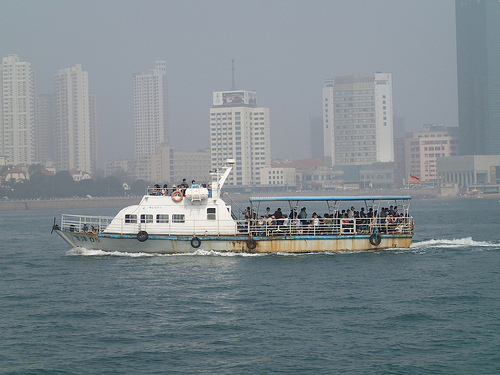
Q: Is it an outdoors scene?
A: Yes, it is outdoors.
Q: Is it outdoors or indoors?
A: It is outdoors.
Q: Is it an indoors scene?
A: No, it is outdoors.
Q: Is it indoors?
A: No, it is outdoors.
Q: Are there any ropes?
A: No, there are no ropes.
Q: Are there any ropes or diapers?
A: No, there are no ropes or diapers.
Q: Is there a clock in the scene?
A: No, there are no clocks.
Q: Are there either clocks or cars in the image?
A: No, there are no clocks or cars.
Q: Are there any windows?
A: Yes, there are windows.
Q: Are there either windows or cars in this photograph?
A: Yes, there are windows.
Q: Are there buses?
A: No, there are no buses.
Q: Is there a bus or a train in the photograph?
A: No, there are no buses or trains.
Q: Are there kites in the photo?
A: No, there are no kites.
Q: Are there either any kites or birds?
A: No, there are no kites or birds.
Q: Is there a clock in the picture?
A: No, there are no clocks.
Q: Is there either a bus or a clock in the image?
A: No, there are no clocks or buses.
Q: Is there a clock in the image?
A: No, there are no clocks.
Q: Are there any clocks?
A: No, there are no clocks.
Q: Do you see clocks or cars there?
A: No, there are no clocks or cars.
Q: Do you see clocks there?
A: No, there are no clocks.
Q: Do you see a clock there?
A: No, there are no clocks.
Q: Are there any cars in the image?
A: No, there are no cars.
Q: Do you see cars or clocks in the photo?
A: No, there are no cars or clocks.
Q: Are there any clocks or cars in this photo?
A: No, there are no cars or clocks.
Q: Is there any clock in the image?
A: No, there are no clocks.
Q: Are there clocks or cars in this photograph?
A: No, there are no cars or clocks.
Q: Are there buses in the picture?
A: No, there are no buses.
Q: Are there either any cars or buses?
A: No, there are no buses or cars.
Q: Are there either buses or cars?
A: No, there are no buses or cars.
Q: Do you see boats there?
A: Yes, there is a boat.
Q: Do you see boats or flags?
A: Yes, there is a boat.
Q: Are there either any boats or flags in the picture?
A: Yes, there is a boat.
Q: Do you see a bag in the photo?
A: No, there are no bags.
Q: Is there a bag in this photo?
A: No, there are no bags.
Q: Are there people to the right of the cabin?
A: Yes, there are people to the right of the cabin.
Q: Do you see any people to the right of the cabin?
A: Yes, there are people to the right of the cabin.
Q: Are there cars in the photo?
A: No, there are no cars.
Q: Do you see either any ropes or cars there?
A: No, there are no cars or ropes.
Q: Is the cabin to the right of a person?
A: No, the cabin is to the left of a person.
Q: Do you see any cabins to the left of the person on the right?
A: Yes, there is a cabin to the left of the person.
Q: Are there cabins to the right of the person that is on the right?
A: No, the cabin is to the left of the person.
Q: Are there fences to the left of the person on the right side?
A: No, there is a cabin to the left of the person.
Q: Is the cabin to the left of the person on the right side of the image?
A: Yes, the cabin is to the left of the person.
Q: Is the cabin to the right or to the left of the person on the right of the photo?
A: The cabin is to the left of the person.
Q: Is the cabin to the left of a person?
A: Yes, the cabin is to the left of a person.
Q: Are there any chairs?
A: No, there are no chairs.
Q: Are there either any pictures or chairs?
A: No, there are no chairs or pictures.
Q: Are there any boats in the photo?
A: Yes, there is a boat.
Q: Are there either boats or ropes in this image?
A: Yes, there is a boat.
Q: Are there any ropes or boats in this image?
A: Yes, there is a boat.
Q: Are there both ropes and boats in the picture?
A: No, there is a boat but no ropes.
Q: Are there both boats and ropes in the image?
A: No, there is a boat but no ropes.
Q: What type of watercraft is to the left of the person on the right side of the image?
A: The watercraft is a boat.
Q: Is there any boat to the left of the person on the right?
A: Yes, there is a boat to the left of the person.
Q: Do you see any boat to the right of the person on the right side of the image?
A: No, the boat is to the left of the person.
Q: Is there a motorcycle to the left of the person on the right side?
A: No, there is a boat to the left of the person.